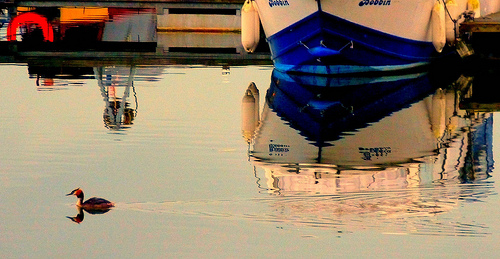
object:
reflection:
[29, 66, 70, 92]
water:
[0, 63, 498, 258]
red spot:
[74, 190, 79, 195]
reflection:
[62, 206, 115, 225]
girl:
[122, 108, 134, 126]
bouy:
[240, 0, 256, 52]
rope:
[442, 5, 467, 23]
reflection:
[90, 62, 140, 133]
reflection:
[237, 67, 495, 236]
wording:
[266, 0, 291, 8]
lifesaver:
[0, 11, 54, 46]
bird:
[64, 187, 115, 208]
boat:
[237, 0, 481, 73]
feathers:
[92, 200, 101, 204]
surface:
[121, 79, 500, 256]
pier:
[459, 10, 499, 71]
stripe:
[157, 28, 245, 34]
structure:
[154, 3, 241, 54]